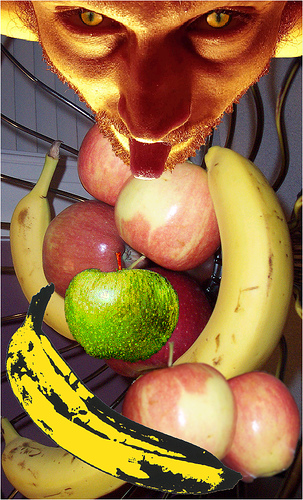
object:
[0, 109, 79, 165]
bar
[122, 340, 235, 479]
apples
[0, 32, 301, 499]
fruit holder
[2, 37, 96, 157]
panels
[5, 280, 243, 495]
banana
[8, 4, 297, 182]
man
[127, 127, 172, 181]
tongue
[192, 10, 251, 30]
eyes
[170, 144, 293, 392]
banana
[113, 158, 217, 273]
apples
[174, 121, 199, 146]
stubble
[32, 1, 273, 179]
face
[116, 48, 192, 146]
nose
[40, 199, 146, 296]
apple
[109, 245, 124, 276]
stem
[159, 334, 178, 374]
stem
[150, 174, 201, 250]
abrasions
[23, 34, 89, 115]
side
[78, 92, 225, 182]
beard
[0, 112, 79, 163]
black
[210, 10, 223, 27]
pupils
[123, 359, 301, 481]
two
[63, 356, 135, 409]
silver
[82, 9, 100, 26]
pupil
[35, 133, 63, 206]
stem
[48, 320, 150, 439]
stand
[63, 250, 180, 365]
fruit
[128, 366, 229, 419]
top